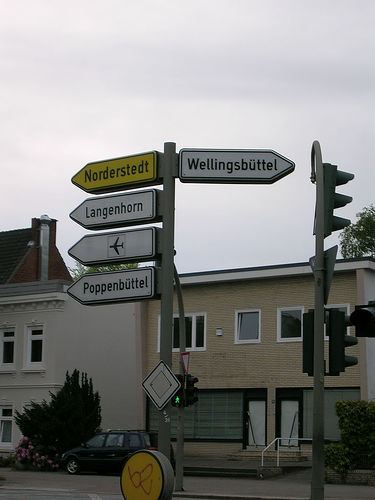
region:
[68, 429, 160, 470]
A car by the building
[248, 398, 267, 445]
A door on the building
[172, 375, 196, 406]
A traffic light by the road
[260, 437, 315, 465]
A white railing by the stairs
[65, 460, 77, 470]
The front wheels on the car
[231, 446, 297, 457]
Stairs by the building doors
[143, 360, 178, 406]
A white sign by the road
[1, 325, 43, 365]
Windows on the building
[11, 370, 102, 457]
A tree by the car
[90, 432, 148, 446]
Windows on the car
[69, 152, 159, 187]
yellow street sign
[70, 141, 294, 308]
four white street signs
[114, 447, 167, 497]
round yellow street sign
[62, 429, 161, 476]
black car parked on street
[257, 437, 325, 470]
white railing on sidewalk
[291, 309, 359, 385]
black traffic signals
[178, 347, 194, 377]
red and white triangle shaped sign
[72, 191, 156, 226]
black lettering on white sign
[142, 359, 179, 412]
diamond shaped white sign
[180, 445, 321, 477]
sidewalk in front of building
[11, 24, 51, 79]
white clouds in blue sky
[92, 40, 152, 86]
white clouds in blue sky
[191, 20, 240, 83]
white clouds in blue sky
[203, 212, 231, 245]
white clouds in blue sky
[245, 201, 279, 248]
white clouds in blue sky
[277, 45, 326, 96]
white clouds in blue sky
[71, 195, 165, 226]
black and white street sign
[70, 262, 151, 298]
black and white street sign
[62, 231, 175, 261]
black and white street sign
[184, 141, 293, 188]
black and white street sign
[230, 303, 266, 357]
Small white window of building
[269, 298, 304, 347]
Small white window of building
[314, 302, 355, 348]
Small white window of building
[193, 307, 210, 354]
Small white window of building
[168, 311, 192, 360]
Small white window of building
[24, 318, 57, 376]
Small white window of building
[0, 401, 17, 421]
Small white window of building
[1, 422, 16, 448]
Small white window of building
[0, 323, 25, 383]
Small white window of building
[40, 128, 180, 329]
White signs on pole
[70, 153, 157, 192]
yellow arrow sign on post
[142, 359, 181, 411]
white triangular sign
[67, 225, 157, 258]
white sign with airplane on it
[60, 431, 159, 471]
car parked in front of building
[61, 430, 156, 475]
black car in front of building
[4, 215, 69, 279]
high rise part of roof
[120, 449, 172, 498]
circular yellow sign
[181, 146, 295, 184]
sign pointing to the right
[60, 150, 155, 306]
four signs pointing to the left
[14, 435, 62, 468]
purple flowers in front of car